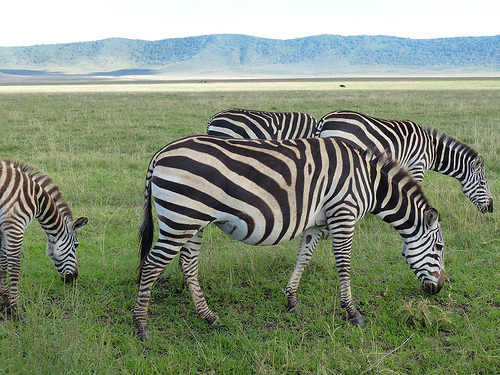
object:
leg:
[327, 213, 365, 326]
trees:
[7, 27, 495, 84]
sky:
[5, 6, 493, 42]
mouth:
[425, 276, 446, 296]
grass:
[2, 90, 499, 373]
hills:
[0, 32, 497, 74]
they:
[133, 107, 492, 339]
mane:
[422, 123, 475, 163]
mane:
[365, 142, 434, 209]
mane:
[2, 157, 73, 218]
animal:
[336, 80, 350, 90]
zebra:
[320, 101, 490, 203]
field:
[4, 86, 494, 373]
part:
[246, 271, 270, 300]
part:
[254, 263, 275, 290]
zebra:
[129, 135, 446, 339]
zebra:
[0, 153, 87, 320]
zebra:
[208, 108, 318, 139]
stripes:
[202, 153, 320, 240]